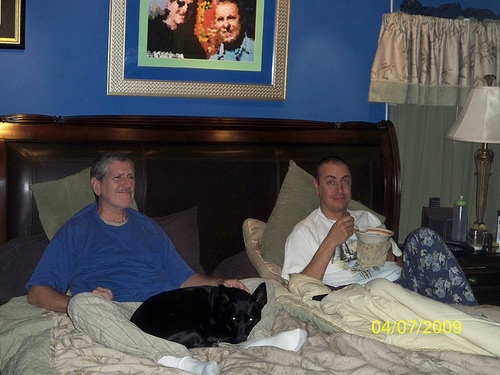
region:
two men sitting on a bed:
[75, 146, 394, 282]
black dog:
[130, 281, 277, 358]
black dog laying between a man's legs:
[68, 282, 300, 372]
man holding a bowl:
[347, 211, 402, 250]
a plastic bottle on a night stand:
[447, 191, 468, 243]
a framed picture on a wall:
[86, 0, 309, 105]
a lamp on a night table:
[448, 75, 498, 235]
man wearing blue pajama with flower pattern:
[401, 217, 480, 319]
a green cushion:
[259, 160, 327, 251]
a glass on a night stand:
[466, 227, 491, 252]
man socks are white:
[274, 333, 281, 348]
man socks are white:
[264, 335, 284, 354]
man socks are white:
[284, 325, 296, 352]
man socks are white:
[282, 341, 292, 352]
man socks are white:
[285, 335, 290, 348]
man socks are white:
[282, 333, 291, 350]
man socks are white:
[286, 333, 295, 360]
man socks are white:
[293, 331, 304, 350]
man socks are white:
[273, 329, 290, 356]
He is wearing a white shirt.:
[283, 166, 408, 290]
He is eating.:
[276, 146, 417, 303]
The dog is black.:
[130, 281, 294, 368]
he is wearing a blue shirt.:
[32, 142, 187, 329]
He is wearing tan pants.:
[20, 141, 227, 372]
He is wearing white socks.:
[156, 305, 308, 373]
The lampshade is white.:
[450, 65, 498, 160]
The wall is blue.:
[299, 16, 360, 103]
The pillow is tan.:
[249, 151, 350, 279]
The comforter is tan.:
[263, 291, 483, 358]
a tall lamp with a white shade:
[450, 83, 497, 245]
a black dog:
[116, 280, 266, 348]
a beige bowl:
[352, 223, 392, 243]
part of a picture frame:
[105, 2, 299, 99]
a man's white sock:
[243, 330, 305, 352]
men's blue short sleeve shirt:
[28, 203, 192, 298]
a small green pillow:
[30, 167, 137, 234]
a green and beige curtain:
[365, 11, 498, 107]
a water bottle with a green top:
[452, 191, 469, 246]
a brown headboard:
[0, 116, 399, 271]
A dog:
[116, 269, 303, 373]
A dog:
[188, 249, 287, 366]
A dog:
[239, 311, 282, 356]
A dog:
[151, 216, 270, 352]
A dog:
[134, 256, 214, 365]